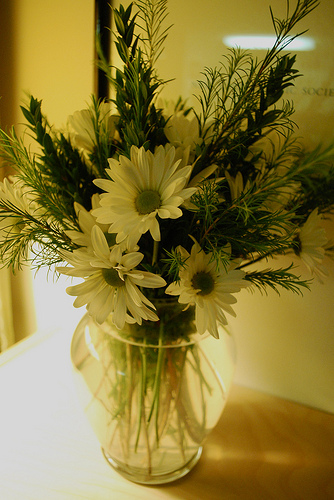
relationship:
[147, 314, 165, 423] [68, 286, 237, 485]
stem inside vase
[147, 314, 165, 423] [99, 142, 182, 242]
stem of flower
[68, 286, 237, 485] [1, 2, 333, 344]
vase of flowers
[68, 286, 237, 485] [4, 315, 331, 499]
vase on table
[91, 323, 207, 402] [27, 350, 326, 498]
vase on table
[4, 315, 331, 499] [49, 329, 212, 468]
table beneath vase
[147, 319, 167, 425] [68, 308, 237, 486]
stem inside vase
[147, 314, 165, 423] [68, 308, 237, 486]
stem inside vase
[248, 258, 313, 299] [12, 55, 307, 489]
green leaves on plant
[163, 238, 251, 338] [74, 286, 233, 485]
flower in vase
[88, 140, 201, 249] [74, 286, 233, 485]
flower in vase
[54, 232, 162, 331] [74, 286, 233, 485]
flower in vase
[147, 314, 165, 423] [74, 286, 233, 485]
stem in vase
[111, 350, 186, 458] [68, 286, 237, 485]
water in vase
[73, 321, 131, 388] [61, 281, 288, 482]
light reflecting on vase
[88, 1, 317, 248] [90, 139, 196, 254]
picture behind flower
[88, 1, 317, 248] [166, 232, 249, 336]
picture behind flower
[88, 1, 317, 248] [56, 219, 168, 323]
picture behind flower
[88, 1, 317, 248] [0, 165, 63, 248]
picture behind flower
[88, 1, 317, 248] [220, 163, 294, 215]
picture behind flower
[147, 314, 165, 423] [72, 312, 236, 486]
stem in water